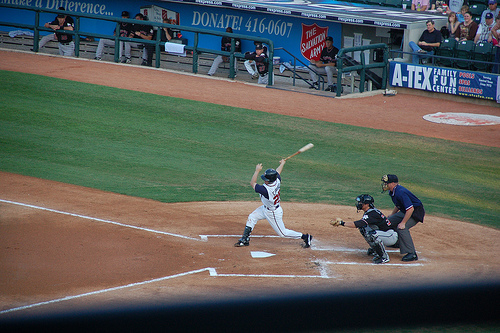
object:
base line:
[0, 195, 202, 248]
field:
[0, 50, 498, 331]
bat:
[279, 140, 314, 161]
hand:
[279, 158, 288, 165]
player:
[233, 159, 312, 250]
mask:
[351, 195, 363, 214]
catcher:
[328, 192, 397, 264]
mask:
[379, 174, 390, 193]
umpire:
[377, 172, 432, 261]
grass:
[1, 69, 499, 231]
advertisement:
[386, 60, 499, 105]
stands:
[2, 1, 499, 107]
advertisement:
[1, 1, 344, 68]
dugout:
[0, 2, 392, 100]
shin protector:
[239, 224, 255, 241]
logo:
[299, 22, 333, 64]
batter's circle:
[419, 109, 499, 129]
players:
[243, 45, 273, 86]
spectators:
[406, 18, 443, 65]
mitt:
[328, 216, 342, 228]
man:
[244, 40, 273, 88]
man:
[43, 12, 81, 58]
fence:
[1, 3, 268, 84]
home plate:
[248, 248, 276, 260]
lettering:
[188, 9, 202, 27]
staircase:
[264, 38, 359, 99]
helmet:
[259, 168, 276, 185]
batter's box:
[198, 229, 330, 278]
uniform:
[243, 182, 299, 239]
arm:
[340, 214, 368, 229]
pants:
[385, 208, 419, 254]